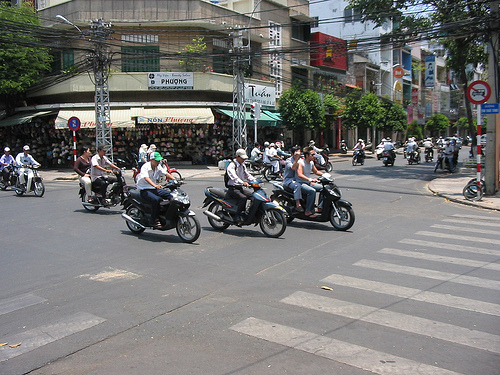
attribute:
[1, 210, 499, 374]
lines — dirty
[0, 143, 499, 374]
street — paved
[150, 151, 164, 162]
hat — green, white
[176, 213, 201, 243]
wheel — black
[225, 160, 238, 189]
backpack — black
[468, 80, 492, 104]
sign — red, white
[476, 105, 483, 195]
pole — red, white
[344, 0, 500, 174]
tree — green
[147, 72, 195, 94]
sign — white, black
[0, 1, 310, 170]
building — large, beige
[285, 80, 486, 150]
trees — green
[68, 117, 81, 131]
sign — blue, red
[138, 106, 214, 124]
awning — yellow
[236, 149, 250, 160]
hat — white